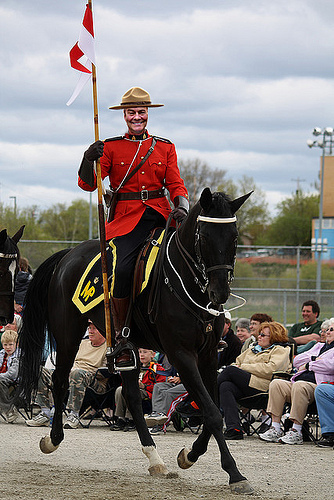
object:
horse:
[19, 188, 254, 497]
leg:
[176, 353, 246, 486]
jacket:
[79, 128, 188, 240]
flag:
[64, 1, 96, 106]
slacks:
[290, 421, 302, 434]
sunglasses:
[258, 332, 268, 340]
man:
[76, 87, 190, 367]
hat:
[107, 85, 164, 110]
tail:
[14, 249, 73, 410]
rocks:
[57, 465, 137, 493]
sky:
[0, 0, 334, 216]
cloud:
[19, 19, 92, 171]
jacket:
[229, 340, 292, 392]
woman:
[216, 320, 292, 440]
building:
[311, 153, 332, 268]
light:
[307, 125, 333, 152]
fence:
[228, 246, 333, 328]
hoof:
[228, 471, 251, 489]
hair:
[258, 319, 289, 344]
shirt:
[291, 319, 328, 344]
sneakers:
[281, 427, 301, 447]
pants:
[38, 344, 80, 453]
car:
[257, 246, 270, 258]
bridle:
[162, 220, 208, 328]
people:
[313, 385, 334, 444]